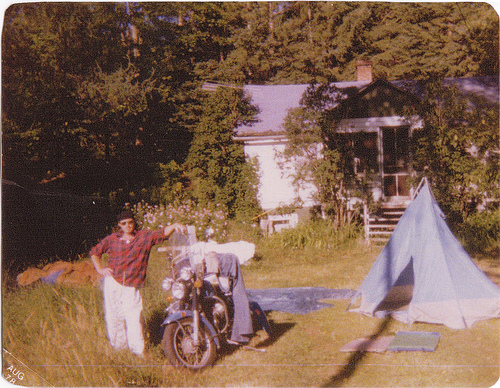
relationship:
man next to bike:
[89, 211, 187, 355] [157, 225, 256, 374]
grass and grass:
[7, 297, 106, 382] [19, 283, 122, 376]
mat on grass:
[349, 330, 385, 359] [263, 368, 342, 386]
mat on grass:
[392, 326, 442, 355] [263, 368, 342, 386]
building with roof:
[202, 60, 500, 234] [234, 72, 409, 140]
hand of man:
[147, 214, 194, 238] [91, 211, 167, 347]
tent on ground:
[355, 173, 498, 326] [280, 297, 372, 364]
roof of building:
[204, 77, 496, 137] [195, 56, 499, 233]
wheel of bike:
[161, 314, 229, 374] [154, 242, 271, 371]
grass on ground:
[7, 297, 106, 382] [11, 239, 490, 383]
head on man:
[116, 208, 136, 234] [71, 220, 179, 344]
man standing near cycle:
[83, 204, 185, 366] [150, 217, 285, 379]